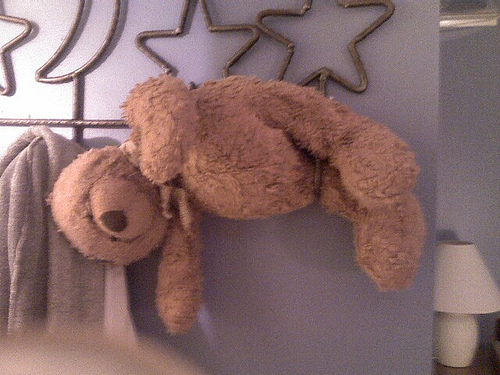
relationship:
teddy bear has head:
[43, 73, 428, 339] [39, 146, 170, 270]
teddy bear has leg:
[43, 73, 428, 339] [321, 164, 427, 294]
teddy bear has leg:
[43, 73, 428, 339] [287, 81, 422, 210]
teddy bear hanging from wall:
[43, 73, 428, 339] [1, 0, 440, 373]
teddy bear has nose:
[43, 73, 428, 339] [100, 210, 129, 233]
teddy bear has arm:
[43, 73, 428, 339] [118, 71, 201, 187]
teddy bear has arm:
[43, 73, 428, 339] [156, 214, 206, 340]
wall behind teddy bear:
[1, 0, 440, 373] [43, 73, 428, 339]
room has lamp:
[2, 1, 499, 373] [431, 241, 498, 368]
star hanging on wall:
[254, 0, 395, 93] [1, 0, 440, 373]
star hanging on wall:
[136, 0, 262, 77] [1, 0, 440, 373]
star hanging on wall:
[0, 1, 33, 97] [1, 0, 440, 373]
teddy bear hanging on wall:
[43, 73, 428, 339] [1, 0, 440, 373]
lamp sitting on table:
[431, 241, 498, 368] [431, 341, 499, 374]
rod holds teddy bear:
[0, 0, 394, 200] [43, 73, 428, 339]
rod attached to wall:
[0, 0, 394, 200] [1, 0, 440, 373]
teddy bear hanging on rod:
[43, 73, 428, 339] [0, 0, 394, 200]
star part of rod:
[254, 0, 395, 93] [0, 0, 394, 200]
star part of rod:
[136, 0, 262, 77] [0, 0, 394, 200]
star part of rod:
[0, 1, 33, 97] [0, 0, 394, 200]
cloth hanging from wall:
[0, 125, 106, 342] [1, 0, 440, 373]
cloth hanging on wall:
[0, 125, 106, 342] [1, 0, 440, 373]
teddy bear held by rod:
[43, 73, 428, 339] [0, 0, 394, 200]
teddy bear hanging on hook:
[43, 73, 428, 339] [312, 75, 328, 202]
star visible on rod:
[254, 0, 395, 93] [0, 0, 394, 200]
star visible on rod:
[136, 0, 262, 77] [0, 0, 394, 200]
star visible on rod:
[0, 1, 33, 97] [0, 0, 394, 200]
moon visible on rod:
[34, 1, 122, 84] [0, 0, 394, 200]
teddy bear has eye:
[43, 73, 428, 339] [87, 213, 94, 221]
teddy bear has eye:
[43, 73, 428, 339] [108, 234, 115, 242]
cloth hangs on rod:
[0, 125, 106, 342] [0, 0, 394, 200]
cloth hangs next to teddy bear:
[0, 125, 106, 342] [43, 73, 428, 339]